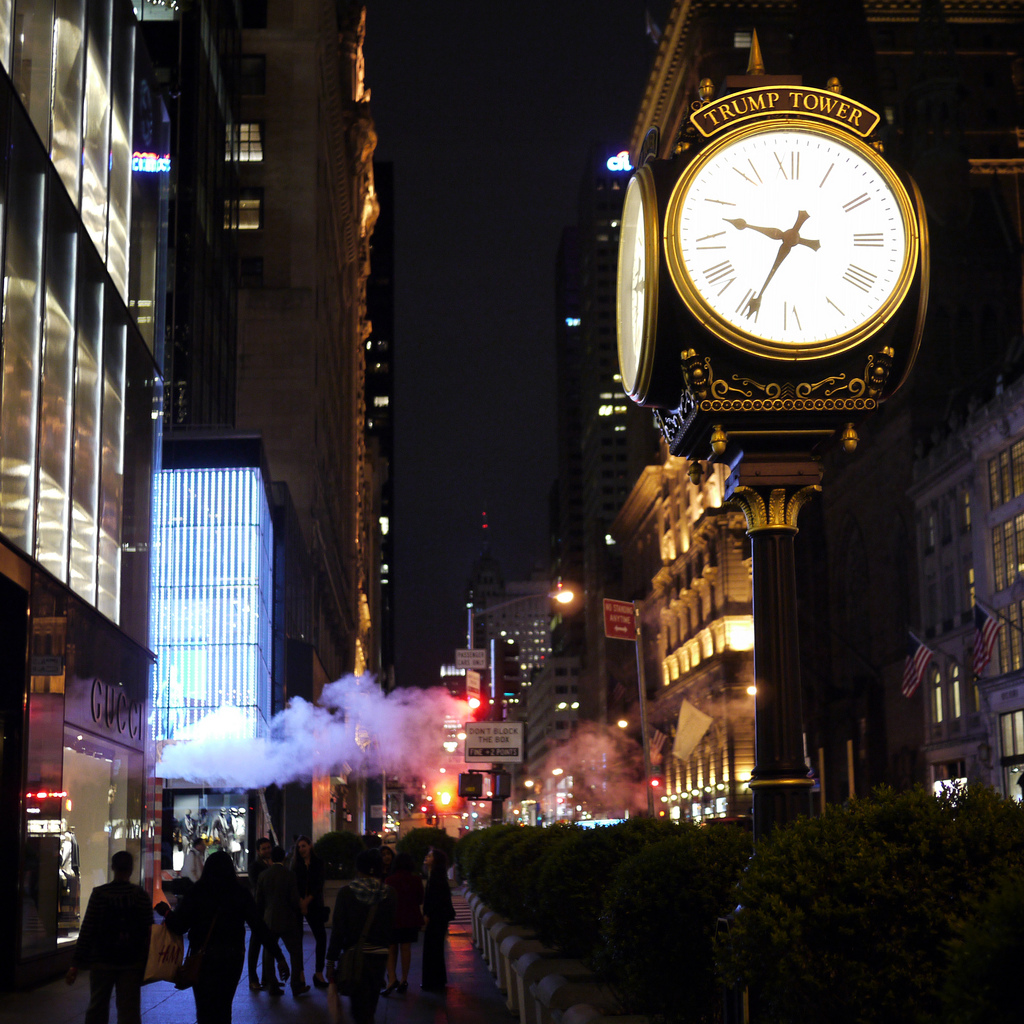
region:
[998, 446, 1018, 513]
window facing busy street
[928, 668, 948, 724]
window facing busy street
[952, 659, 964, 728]
window facing busy street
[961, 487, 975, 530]
window facing busy street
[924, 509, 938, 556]
window facing busy street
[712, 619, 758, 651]
window on the building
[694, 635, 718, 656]
window on the building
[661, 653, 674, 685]
window on the building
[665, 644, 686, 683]
window on the building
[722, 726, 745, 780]
window on the building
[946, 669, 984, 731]
window on the building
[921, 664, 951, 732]
window on the building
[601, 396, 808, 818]
Building by a road.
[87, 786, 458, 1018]
People walking on a sidewalk.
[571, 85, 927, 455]
Clock on a pole.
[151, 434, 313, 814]
Building light up by a sidewalk.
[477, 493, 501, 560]
Light on top of a building.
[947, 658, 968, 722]
A window on a building.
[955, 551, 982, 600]
A window on a building.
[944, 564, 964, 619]
A window on a building.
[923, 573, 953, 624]
A window on a building.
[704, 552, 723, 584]
A window on a building.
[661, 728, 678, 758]
A window on a building.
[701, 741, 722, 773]
A window on a building.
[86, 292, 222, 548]
a window on the building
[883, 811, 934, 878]
green leaves on the bush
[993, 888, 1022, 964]
green leaves on the bush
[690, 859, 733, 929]
green leaves on the bush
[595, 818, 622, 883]
green leaves on the bush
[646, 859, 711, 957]
green leaves on the bush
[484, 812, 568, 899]
green leaves on the bush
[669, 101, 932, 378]
clock on the pole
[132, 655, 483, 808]
steam coming from the building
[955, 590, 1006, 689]
american flag on the building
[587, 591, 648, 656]
parking sign is red and white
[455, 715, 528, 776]
traffic sign is black and white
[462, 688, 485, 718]
traffic light is red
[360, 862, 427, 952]
woman carrying a backpack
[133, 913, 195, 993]
woman carrying a white bag